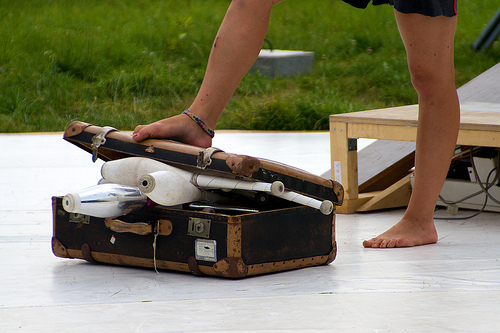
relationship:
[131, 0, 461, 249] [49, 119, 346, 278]
person standing on box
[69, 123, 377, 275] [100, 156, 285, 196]
box contains bowling pin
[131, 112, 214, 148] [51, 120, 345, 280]
foot on suitcase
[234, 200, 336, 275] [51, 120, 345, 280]
side of a suitcase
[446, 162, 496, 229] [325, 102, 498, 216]
cords under stage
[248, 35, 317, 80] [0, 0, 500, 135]
metal box on grass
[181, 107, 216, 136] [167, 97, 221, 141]
band on an ankle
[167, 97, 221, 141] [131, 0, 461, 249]
ankle of a person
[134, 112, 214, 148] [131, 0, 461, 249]
foot of a person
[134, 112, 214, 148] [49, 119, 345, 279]
foot on a box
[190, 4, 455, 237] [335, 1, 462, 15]
person wearing shorts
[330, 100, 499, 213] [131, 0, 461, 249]
wooden bench behind person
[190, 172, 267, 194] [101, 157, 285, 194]
neck on bowling pin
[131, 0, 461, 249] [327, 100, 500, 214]
person in front of wooden bench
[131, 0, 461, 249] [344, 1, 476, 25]
person wears shorts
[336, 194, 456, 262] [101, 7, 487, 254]
foot of person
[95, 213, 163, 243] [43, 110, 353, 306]
handle of suitcase